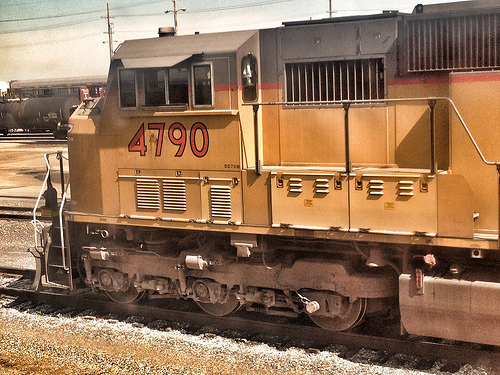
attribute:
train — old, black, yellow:
[21, 1, 500, 357]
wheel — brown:
[196, 296, 242, 320]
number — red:
[123, 121, 213, 165]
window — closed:
[193, 64, 215, 106]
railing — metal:
[285, 61, 381, 98]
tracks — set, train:
[3, 270, 496, 370]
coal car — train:
[0, 90, 67, 138]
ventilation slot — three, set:
[312, 179, 330, 197]